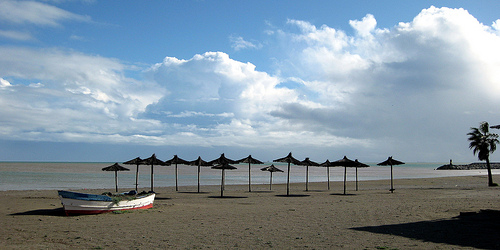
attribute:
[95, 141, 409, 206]
dark umbrellas — dark 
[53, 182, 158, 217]
boat — small , red, white , blue 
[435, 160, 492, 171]
flat land — flat 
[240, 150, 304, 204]
shorter umbrella — shorter 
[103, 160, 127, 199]
large umbrella — Large 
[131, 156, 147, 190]
large umbrella — Large 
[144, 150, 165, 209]
large umbrella — Large 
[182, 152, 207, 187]
large umbrella — Large 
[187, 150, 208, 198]
large umbrella — Large 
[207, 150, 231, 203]
large umbrella — Large 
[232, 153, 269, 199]
large umbrella — Large 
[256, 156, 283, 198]
large umbrella — Large 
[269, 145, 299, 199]
large umbrella — Large 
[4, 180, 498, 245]
sand — flat , brown 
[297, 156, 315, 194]
large umbrella — Large 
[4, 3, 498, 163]
blue sky — Blue , puffy 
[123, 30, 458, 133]
white clouds — white , big 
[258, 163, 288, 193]
opened umbrella — opened , smallest 